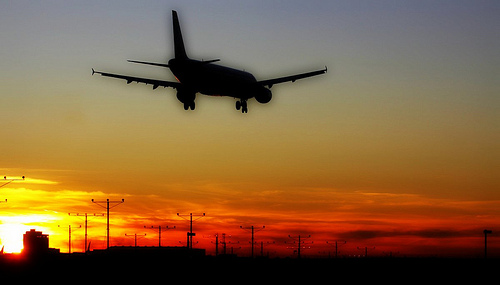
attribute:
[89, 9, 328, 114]
plane — dark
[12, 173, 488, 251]
clouds — red, orange, whispy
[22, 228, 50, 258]
building — tall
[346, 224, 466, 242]
shade in the sky — green, eerie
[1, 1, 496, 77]
blue sky — yellow, red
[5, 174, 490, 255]
sunset — beautiful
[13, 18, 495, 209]
sky — evening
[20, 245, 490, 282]
land — flat